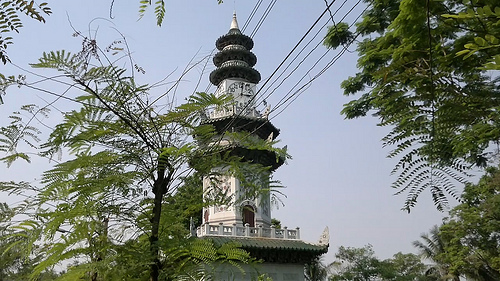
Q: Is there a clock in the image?
A: Yes, there is a clock.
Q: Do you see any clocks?
A: Yes, there is a clock.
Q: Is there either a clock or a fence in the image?
A: Yes, there is a clock.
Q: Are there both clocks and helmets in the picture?
A: No, there is a clock but no helmets.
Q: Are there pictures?
A: No, there are no pictures.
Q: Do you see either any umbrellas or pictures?
A: No, there are no pictures or umbrellas.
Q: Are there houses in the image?
A: No, there are no houses.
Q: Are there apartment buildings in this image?
A: No, there are no apartment buildings.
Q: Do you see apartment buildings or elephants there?
A: No, there are no apartment buildings or elephants.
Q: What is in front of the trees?
A: The temple is in front of the trees.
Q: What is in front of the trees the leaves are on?
A: The temple is in front of the trees.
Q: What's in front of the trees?
A: The temple is in front of the trees.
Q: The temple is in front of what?
A: The temple is in front of the trees.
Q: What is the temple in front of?
A: The temple is in front of the trees.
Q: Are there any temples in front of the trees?
A: Yes, there is a temple in front of the trees.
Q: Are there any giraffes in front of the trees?
A: No, there is a temple in front of the trees.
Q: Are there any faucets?
A: No, there are no faucets.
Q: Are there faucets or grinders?
A: No, there are no faucets or grinders.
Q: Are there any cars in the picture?
A: No, there are no cars.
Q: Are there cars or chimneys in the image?
A: No, there are no cars or chimneys.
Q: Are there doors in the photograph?
A: Yes, there is a door.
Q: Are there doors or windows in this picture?
A: Yes, there is a door.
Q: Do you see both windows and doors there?
A: No, there is a door but no windows.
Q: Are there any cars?
A: No, there are no cars.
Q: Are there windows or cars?
A: No, there are no cars or windows.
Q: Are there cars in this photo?
A: No, there are no cars.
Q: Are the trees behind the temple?
A: Yes, the trees are behind the temple.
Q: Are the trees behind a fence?
A: No, the trees are behind the temple.